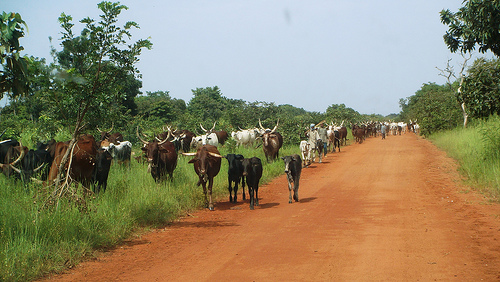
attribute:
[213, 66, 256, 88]
clouds — white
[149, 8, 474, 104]
sky — blue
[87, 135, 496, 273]
road — dirt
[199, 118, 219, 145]
cow — white, large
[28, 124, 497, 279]
road — sandy, dirt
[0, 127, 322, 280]
grass — green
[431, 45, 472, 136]
tree — large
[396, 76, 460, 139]
tree — large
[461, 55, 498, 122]
tree — large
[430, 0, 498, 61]
tree — large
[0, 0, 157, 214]
tree — large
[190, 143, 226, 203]
steer — large, horned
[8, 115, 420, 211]
cattle — large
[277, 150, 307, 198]
cow — white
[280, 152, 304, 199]
cattle — smaller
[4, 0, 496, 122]
sky — blue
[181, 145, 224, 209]
bull — big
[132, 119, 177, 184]
bull — big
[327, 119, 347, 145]
bull — big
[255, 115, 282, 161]
bull — big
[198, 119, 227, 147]
bull — big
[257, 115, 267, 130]
tusk — white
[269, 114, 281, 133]
tusk — white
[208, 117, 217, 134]
tusk — white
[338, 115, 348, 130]
tusk — white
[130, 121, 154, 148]
tusk — white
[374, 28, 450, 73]
clouds — white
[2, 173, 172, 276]
grass — tall